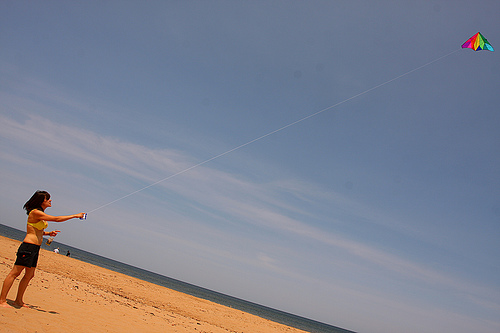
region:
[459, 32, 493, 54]
Colorful kite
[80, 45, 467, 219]
String attached to a colorful kite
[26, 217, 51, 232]
Yellow bikini top of kite flyer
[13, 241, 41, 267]
Dark short on lady kite flyer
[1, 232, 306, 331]
Brown sandy beach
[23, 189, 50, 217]
Long brown hair of lady kite flyer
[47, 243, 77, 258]
Two people along the shore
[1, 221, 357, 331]
The blue ocean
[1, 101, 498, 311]
Light white clouds above the ocean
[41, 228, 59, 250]
Bottle in hand of lady kite flyer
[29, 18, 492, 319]
a popular summer activity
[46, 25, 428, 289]
a wide open sky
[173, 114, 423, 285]
a few whispy clouds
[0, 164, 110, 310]
a woman in shorts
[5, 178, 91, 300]
a dark haired woman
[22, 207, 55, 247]
a bright yellow bikini top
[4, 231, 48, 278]
some dark colored shorts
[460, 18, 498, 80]
a bright multicolored kite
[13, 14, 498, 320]
a woman flying a kite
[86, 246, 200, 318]
a calm blue ocean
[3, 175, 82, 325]
woman in yellow bikini top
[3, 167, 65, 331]
woman is flying a kite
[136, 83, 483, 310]
sly is bright and blue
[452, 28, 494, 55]
multi colored kite in air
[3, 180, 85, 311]
woman on beach flying kite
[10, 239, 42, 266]
man wearing black shorts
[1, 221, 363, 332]
water behind sand is calm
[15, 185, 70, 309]
A person is standing up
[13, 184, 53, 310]
A person is playing.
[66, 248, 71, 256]
A person is playing.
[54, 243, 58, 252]
A person is playing.